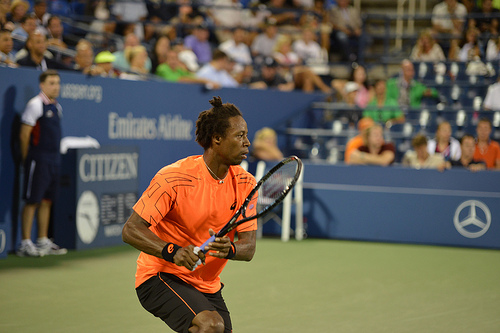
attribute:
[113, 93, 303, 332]
tennis player — playing, focused, male, sweaty, black, preparing, white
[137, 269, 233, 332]
shorts — black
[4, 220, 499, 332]
court — green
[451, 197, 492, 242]
sponsor — mercedes benz, mercedes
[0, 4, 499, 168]
audience — watching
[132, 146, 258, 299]
shirt — orange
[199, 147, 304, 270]
racket — black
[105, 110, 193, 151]
sponsor — white, emirates airlines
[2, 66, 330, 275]
wall — blue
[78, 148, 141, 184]
sponsor — citizen, white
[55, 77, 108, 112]
logo — white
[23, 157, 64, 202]
shorts — dark blue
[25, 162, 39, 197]
stripe — orange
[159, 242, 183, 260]
wristband — black, orange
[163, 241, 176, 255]
design — orange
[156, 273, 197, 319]
stripe — orange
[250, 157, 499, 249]
wall — blue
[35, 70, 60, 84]
hair — brown